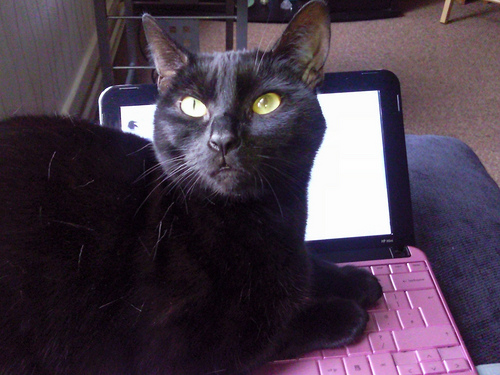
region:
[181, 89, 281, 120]
Two golden cat eyes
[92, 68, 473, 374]
Small netbook powered on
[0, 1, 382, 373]
Black cat sitting on a netbook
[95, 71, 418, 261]
Black frame on screen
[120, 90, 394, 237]
Netbook screen is powered on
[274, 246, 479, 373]
Pink keyboard on netbook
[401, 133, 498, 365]
Dark colored chair cushion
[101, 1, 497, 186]
Light brown short carpet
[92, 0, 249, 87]
Metal furniture legs behind cat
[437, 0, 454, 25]
Wooden chair leg in background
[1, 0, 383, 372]
the cat lying on the laptop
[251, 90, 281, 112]
the eye on the cat's face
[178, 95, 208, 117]
the eye on the cat's face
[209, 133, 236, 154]
the nose on the cat's face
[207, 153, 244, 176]
the mouth on the cat's face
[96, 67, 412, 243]
the top of the laptop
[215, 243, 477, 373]
the bottom of the laptop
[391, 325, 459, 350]
the key on the keyboard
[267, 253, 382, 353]
the cat's two legs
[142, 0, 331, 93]
the ears on the cat's head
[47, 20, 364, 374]
the cat is black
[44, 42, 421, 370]
a cat on the laptop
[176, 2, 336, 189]
the head of a cat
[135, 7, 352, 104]
the ears of a cat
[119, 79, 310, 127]
the eyes of a cat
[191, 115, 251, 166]
a nose of a cat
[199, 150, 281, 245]
the mouth of a cat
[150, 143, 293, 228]
the whiskers of a cat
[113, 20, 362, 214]
the black head of a cat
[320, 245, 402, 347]
the paws of a cat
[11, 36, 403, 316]
the body of a cat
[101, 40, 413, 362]
a cat on a lapyop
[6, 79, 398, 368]
the cat is on the laptop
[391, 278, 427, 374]
the buttons are pink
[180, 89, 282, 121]
the eyes are silver in color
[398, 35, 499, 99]
the carpet is brown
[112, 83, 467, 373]
the laptop is on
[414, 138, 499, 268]
the cushion is grey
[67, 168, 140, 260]
whiskers are on the cat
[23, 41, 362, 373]
the act is looking at the camera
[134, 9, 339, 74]
the ears are standing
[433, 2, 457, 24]
the leg is wooden